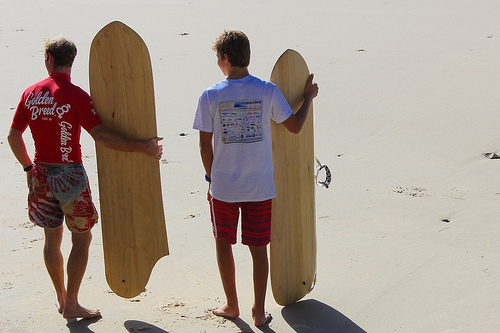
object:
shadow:
[280, 298, 364, 332]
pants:
[28, 162, 99, 233]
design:
[218, 98, 264, 144]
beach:
[338, 267, 392, 289]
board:
[269, 49, 319, 306]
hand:
[303, 73, 318, 100]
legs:
[57, 227, 101, 320]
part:
[58, 121, 74, 163]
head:
[43, 36, 78, 74]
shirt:
[191, 75, 295, 204]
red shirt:
[11, 72, 102, 162]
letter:
[59, 121, 73, 130]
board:
[88, 20, 172, 298]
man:
[191, 27, 319, 328]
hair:
[234, 39, 243, 46]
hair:
[46, 43, 63, 50]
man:
[6, 36, 162, 318]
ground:
[333, 58, 458, 160]